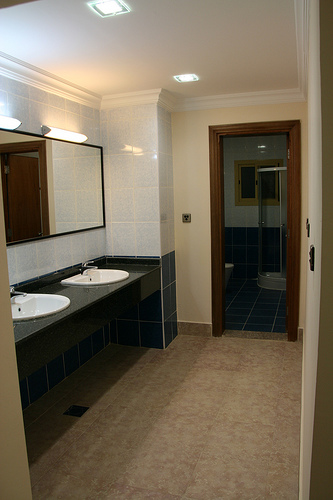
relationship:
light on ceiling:
[93, 0, 119, 17] [2, 4, 321, 96]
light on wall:
[41, 126, 92, 138] [1, 69, 180, 285]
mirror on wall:
[2, 132, 105, 236] [1, 69, 180, 285]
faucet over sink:
[82, 262, 102, 274] [69, 263, 126, 285]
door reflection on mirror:
[6, 146, 47, 230] [2, 132, 105, 236]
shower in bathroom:
[256, 171, 288, 287] [3, 100, 332, 486]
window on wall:
[241, 167, 271, 199] [219, 141, 289, 229]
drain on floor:
[63, 400, 88, 416] [40, 351, 294, 499]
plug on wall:
[180, 214, 193, 226] [1, 69, 180, 285]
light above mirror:
[41, 126, 92, 138] [2, 132, 105, 236]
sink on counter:
[69, 263, 126, 285] [10, 269, 154, 325]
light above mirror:
[93, 0, 119, 17] [2, 132, 105, 236]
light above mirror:
[2, 117, 20, 131] [2, 132, 105, 236]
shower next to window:
[256, 171, 288, 287] [241, 167, 271, 199]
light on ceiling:
[178, 73, 199, 85] [2, 4, 321, 96]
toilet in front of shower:
[221, 261, 232, 281] [256, 171, 288, 287]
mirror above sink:
[2, 132, 105, 236] [69, 263, 126, 285]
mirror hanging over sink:
[2, 132, 105, 236] [69, 263, 126, 285]